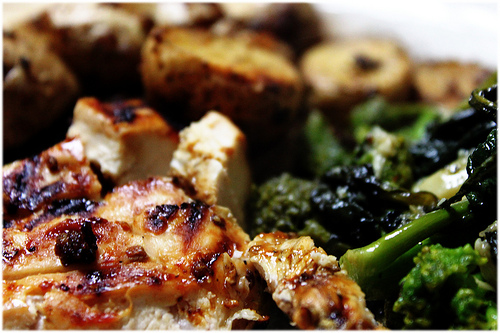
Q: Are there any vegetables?
A: Yes, there are vegetables.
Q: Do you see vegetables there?
A: Yes, there are vegetables.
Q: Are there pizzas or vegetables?
A: Yes, there are vegetables.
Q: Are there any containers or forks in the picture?
A: No, there are no forks or containers.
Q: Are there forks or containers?
A: No, there are no forks or containers.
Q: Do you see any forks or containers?
A: No, there are no forks or containers.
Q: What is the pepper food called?
A: The food is vegetables.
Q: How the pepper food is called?
A: The food is vegetables.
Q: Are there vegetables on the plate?
A: Yes, there are vegetables on the plate.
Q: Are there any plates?
A: Yes, there is a plate.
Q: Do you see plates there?
A: Yes, there is a plate.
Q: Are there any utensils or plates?
A: Yes, there is a plate.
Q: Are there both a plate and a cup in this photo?
A: No, there is a plate but no cups.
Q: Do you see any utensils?
A: No, there are no utensils.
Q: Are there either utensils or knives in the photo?
A: No, there are no utensils or knives.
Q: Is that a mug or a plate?
A: That is a plate.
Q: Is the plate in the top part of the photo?
A: Yes, the plate is in the top of the image.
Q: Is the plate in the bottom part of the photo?
A: No, the plate is in the top of the image.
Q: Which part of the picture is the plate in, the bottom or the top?
A: The plate is in the top of the image.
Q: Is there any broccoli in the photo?
A: Yes, there is broccoli.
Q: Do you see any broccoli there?
A: Yes, there is broccoli.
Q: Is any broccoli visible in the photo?
A: Yes, there is broccoli.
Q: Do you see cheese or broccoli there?
A: Yes, there is broccoli.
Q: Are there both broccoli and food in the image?
A: Yes, there are both broccoli and food.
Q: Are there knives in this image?
A: No, there are no knives.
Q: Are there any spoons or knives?
A: No, there are no knives or spoons.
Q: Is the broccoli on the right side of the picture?
A: Yes, the broccoli is on the right of the image.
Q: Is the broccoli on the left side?
A: No, the broccoli is on the right of the image.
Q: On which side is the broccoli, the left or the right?
A: The broccoli is on the right of the image.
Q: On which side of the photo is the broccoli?
A: The broccoli is on the right of the image.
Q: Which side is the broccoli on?
A: The broccoli is on the right of the image.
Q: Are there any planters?
A: No, there are no planters.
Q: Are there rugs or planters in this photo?
A: No, there are no planters or rugs.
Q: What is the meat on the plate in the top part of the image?
A: The meat is chicken.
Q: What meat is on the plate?
A: The meat is chicken.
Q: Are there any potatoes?
A: Yes, there is a potato.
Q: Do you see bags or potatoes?
A: Yes, there is a potato.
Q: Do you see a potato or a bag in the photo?
A: Yes, there is a potato.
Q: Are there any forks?
A: No, there are no forks.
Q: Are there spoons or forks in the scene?
A: No, there are no forks or spoons.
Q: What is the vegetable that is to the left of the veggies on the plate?
A: The vegetable is a potato.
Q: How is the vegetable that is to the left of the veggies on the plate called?
A: The vegetable is a potato.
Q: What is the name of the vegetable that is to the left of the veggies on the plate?
A: The vegetable is a potato.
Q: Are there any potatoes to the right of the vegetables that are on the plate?
A: No, the potato is to the left of the veggies.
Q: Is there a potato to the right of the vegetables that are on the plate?
A: No, the potato is to the left of the veggies.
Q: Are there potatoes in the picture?
A: Yes, there is a potato.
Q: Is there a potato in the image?
A: Yes, there is a potato.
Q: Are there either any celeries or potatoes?
A: Yes, there is a potato.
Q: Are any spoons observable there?
A: No, there are no spoons.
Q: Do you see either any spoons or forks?
A: No, there are no spoons or forks.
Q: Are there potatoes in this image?
A: Yes, there are potatoes.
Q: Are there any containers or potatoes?
A: Yes, there are potatoes.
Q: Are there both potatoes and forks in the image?
A: No, there are potatoes but no forks.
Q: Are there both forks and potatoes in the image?
A: No, there are potatoes but no forks.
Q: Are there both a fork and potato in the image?
A: No, there are potatoes but no forks.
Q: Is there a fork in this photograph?
A: No, there are no forks.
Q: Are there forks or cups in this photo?
A: No, there are no forks or cups.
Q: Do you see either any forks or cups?
A: No, there are no forks or cups.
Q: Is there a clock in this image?
A: No, there are no clocks.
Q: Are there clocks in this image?
A: No, there are no clocks.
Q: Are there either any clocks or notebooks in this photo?
A: No, there are no clocks or notebooks.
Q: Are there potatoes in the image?
A: Yes, there is a potato.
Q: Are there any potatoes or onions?
A: Yes, there is a potato.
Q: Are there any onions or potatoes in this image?
A: Yes, there is a potato.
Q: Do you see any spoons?
A: No, there are no spoons.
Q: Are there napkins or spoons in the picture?
A: No, there are no spoons or napkins.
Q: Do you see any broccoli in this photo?
A: Yes, there is broccoli.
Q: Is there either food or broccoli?
A: Yes, there is broccoli.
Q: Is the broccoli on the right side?
A: Yes, the broccoli is on the right of the image.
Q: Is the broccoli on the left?
A: No, the broccoli is on the right of the image.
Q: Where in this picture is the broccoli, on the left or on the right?
A: The broccoli is on the right of the image.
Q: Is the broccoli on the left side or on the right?
A: The broccoli is on the right of the image.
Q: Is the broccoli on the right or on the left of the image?
A: The broccoli is on the right of the image.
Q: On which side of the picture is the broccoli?
A: The broccoli is on the right of the image.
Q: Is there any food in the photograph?
A: Yes, there is food.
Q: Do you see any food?
A: Yes, there is food.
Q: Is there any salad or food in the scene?
A: Yes, there is food.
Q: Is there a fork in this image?
A: No, there are no forks.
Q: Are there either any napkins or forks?
A: No, there are no forks or napkins.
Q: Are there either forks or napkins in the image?
A: No, there are no forks or napkins.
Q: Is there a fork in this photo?
A: No, there are no forks.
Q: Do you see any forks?
A: No, there are no forks.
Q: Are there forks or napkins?
A: No, there are no forks or napkins.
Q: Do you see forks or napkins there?
A: No, there are no forks or napkins.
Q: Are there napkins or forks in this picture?
A: No, there are no forks or napkins.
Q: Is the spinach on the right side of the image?
A: Yes, the spinach is on the right of the image.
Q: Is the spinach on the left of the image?
A: No, the spinach is on the right of the image.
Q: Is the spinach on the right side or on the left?
A: The spinach is on the right of the image.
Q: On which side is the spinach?
A: The spinach is on the right of the image.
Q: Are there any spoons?
A: No, there are no spoons.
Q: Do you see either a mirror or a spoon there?
A: No, there are no spoons or mirrors.